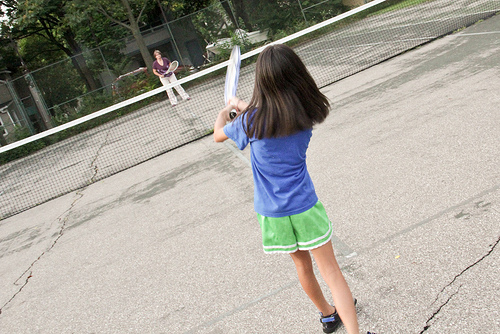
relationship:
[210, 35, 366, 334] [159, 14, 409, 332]
female plays tennis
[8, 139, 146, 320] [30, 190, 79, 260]
cement has crack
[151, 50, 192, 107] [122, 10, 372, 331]
lady plays tennis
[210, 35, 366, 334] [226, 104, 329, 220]
female wears shirt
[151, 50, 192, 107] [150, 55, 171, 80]
lady wears shirt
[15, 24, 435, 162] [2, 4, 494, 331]
net across court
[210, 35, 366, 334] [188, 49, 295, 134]
female with racket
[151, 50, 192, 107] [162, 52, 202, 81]
lady with racket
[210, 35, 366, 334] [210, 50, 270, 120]
female with racket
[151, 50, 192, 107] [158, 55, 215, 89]
lady with racket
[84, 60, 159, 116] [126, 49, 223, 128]
vehicle behind woman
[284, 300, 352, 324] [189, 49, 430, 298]
shoe on girl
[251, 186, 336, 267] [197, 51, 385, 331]
shorts on girl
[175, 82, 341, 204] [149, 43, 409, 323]
shirt on girl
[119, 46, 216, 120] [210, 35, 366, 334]
lady with female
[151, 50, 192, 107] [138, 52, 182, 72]
lady with shirt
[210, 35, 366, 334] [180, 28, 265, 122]
female with racket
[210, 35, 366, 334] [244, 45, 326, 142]
female with hair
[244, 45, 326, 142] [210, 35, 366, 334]
hair on female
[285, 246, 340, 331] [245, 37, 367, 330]
leg on girl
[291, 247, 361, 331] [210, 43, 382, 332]
leg on girl